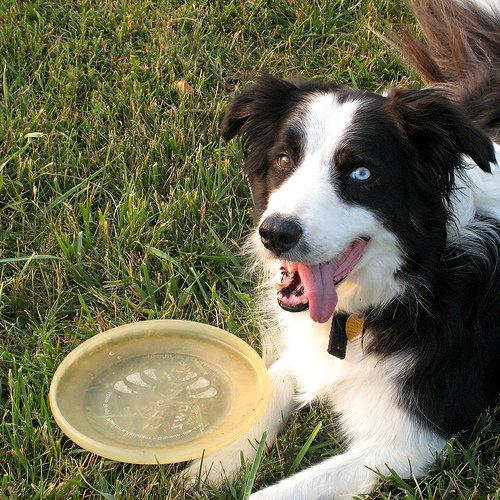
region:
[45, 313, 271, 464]
a pale yellow frisbee on the ground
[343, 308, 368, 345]
a gold tag on a dog's collar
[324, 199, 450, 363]
a black collar on a dog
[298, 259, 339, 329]
a pink tongue hanging out of a dog's mouth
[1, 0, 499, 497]
cut green grass under a dog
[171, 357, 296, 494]
the leg of a dog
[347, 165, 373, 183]
a blue eye on a dog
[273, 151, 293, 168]
a brown eye on a dog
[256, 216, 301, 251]
a black nose on a dog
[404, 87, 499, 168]
a black ear on a dog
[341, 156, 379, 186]
Blue eye on dog.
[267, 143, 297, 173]
Brown eye on dog.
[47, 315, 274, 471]
Frisbee in the grass.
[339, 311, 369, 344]
Tag on collar.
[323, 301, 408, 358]
black collar on the dog.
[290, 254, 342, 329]
Pink tongue on dog.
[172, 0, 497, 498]
Dog laying in the grass.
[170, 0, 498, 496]
Black and white hair on the dog.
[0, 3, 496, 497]
Green grass covering the ground.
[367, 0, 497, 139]
Brown hair on dog's tail.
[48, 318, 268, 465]
a Frisbee disc on the ground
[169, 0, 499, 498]
a black and white dog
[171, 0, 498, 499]
a white and black dog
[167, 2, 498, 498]
a black and white dog lying down on the grass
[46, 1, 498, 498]
a dog lying down on the ground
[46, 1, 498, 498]
a Frisbee disc in front of the dog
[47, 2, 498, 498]
a dog beside a Frisbee disk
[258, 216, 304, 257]
the dog's black nose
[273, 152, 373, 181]
a brown eye and blue eye dog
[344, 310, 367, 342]
a metal tag on the dog's collar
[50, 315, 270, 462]
frisbee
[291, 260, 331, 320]
pink dog tongue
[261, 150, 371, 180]
two eyes of different colors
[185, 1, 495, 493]
black and white border collie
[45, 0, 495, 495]
dog tired from frisbee playing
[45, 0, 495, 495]
happy dog with frisbee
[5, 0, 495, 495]
border collie taking break from playing frisbee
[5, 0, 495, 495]
border collie with frisbee on grass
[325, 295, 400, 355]
dog collar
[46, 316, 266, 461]
flying dog disc toy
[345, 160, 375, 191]
Blue eye of a border collie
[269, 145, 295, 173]
Brown eye of a border collie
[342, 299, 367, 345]
Tag on a dog collar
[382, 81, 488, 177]
Black ear of a dog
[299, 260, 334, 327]
Pink tongue of a dog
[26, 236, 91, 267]
Green grass in a yard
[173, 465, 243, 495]
White paw of a dog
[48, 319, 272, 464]
a yellow frisbee on the the grass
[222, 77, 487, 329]
the dog's tongue is hanging out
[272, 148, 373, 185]
one eye is blue and the other is brown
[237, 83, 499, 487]
the dog is black and white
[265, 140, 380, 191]
Brown and blue dog eyes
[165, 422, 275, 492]
A white paw of the dog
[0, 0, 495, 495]
Dog laying on the green grass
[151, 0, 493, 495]
A brown and white dog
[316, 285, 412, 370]
Black collar and a gold tag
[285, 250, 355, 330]
The tongue of a dog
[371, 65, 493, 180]
Left ear of a dog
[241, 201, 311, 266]
Black nose of a dog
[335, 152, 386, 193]
A dog's left eye is blue